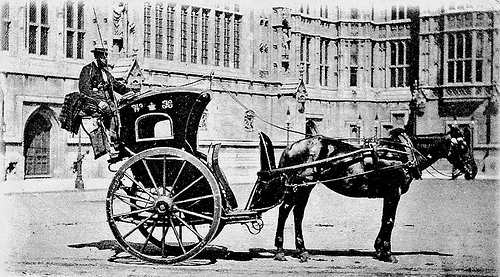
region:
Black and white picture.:
[33, 25, 462, 248]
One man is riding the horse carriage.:
[53, 41, 404, 256]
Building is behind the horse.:
[62, 25, 488, 240]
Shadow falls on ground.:
[136, 217, 416, 272]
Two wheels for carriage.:
[60, 47, 235, 257]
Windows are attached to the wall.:
[15, 6, 192, 76]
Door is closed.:
[6, 95, 71, 195]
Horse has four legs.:
[257, 205, 419, 260]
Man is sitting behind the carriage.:
[35, 36, 145, 142]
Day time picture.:
[23, 35, 471, 260]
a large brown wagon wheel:
[106, 147, 221, 263]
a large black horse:
[276, 125, 478, 261]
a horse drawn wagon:
[103, 86, 263, 263]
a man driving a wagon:
[57, 46, 138, 161]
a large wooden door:
[23, 103, 60, 178]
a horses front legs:
[375, 192, 402, 262]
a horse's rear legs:
[272, 188, 315, 261]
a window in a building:
[387, 40, 410, 84]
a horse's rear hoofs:
[273, 246, 311, 261]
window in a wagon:
[130, 113, 178, 141]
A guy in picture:
[50, 40, 135, 165]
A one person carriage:
[43, 30, 253, 260]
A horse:
[241, 90, 475, 275]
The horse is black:
[247, 77, 486, 271]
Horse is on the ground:
[221, 80, 486, 275]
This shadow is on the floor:
[52, 203, 459, 274]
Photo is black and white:
[28, 17, 483, 259]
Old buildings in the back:
[23, 8, 496, 212]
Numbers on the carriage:
[123, 90, 183, 129]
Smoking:
[86, 48, 131, 80]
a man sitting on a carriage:
[69, 46, 125, 153]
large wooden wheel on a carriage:
[105, 146, 221, 263]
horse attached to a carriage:
[107, 93, 479, 263]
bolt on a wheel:
[157, 202, 166, 209]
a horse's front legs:
[372, 193, 399, 264]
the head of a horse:
[442, 124, 477, 179]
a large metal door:
[18, 108, 52, 174]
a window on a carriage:
[130, 113, 175, 140]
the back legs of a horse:
[272, 186, 309, 259]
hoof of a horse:
[271, 249, 288, 261]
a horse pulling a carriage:
[71, 27, 498, 234]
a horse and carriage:
[65, 24, 452, 274]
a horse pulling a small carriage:
[83, 35, 469, 267]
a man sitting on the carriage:
[59, 25, 214, 212]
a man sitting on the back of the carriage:
[21, 32, 178, 166]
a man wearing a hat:
[32, 22, 201, 156]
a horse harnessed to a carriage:
[69, 32, 496, 257]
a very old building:
[3, 2, 440, 152]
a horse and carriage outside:
[44, 27, 498, 271]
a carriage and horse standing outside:
[60, 16, 450, 275]